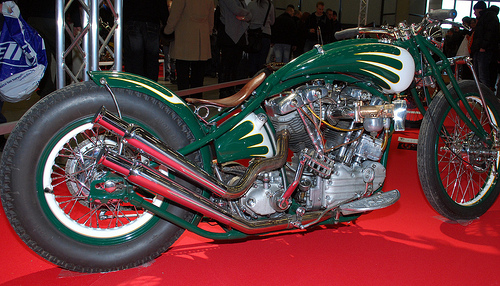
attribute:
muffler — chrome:
[95, 152, 307, 232]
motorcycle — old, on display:
[91, 33, 398, 242]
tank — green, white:
[239, 37, 418, 118]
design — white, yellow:
[356, 42, 412, 92]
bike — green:
[64, 34, 426, 244]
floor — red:
[11, 62, 486, 283]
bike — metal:
[0, 10, 497, 272]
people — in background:
[130, 0, 285, 89]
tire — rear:
[1, 82, 205, 270]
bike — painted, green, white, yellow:
[268, 39, 417, 101]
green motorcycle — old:
[2, 8, 499, 270]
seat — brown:
[176, 61, 292, 125]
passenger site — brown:
[175, 65, 281, 129]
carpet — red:
[18, 167, 496, 284]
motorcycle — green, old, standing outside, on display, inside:
[4, 3, 498, 278]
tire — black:
[2, 90, 199, 250]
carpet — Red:
[264, 250, 469, 280]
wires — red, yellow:
[302, 95, 349, 134]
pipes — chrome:
[82, 107, 287, 267]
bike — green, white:
[32, 29, 496, 249]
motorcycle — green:
[65, 22, 472, 259]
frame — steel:
[94, 38, 425, 243]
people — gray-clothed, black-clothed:
[188, 10, 343, 156]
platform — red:
[0, 49, 498, 283]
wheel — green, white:
[48, 120, 170, 233]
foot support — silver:
[342, 186, 398, 215]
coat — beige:
[164, 0, 217, 60]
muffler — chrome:
[94, 105, 288, 199]